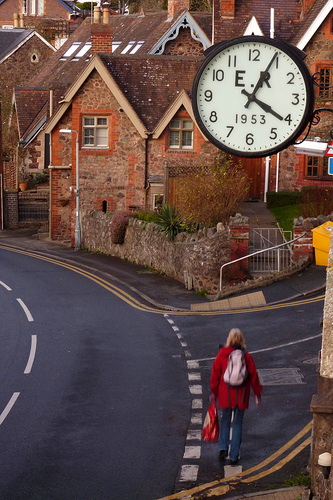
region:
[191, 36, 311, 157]
black and white clock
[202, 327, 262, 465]
person walking in the street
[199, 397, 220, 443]
bag is red and white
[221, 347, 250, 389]
backpack is white and black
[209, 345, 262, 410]
the coat is red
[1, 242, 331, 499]
the road is white and yellow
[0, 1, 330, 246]
houses on hilltop made of stone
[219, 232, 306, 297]
metal bars on stone steps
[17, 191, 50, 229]
brick steps by road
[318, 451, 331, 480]
light sconce on bottom corner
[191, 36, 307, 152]
round clock on right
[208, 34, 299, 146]
digits on white clock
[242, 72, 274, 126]
black arms on clock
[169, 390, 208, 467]
whtie lines on road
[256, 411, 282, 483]
yellow lines on road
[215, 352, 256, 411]
red jacket on woman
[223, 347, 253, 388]
pink backpack on woman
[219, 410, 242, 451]
blue jeans on woman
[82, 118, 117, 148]
small window on house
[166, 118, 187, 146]
small window on house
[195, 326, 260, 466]
woman wearing blue jeans and red jacket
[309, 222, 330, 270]
yellow trash receptacle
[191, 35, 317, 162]
round public clock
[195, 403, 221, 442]
red shopping bag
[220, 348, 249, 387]
light colored backpack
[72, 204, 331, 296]
a fence made of stone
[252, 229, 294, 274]
a metal gate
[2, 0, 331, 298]
a group of brick houses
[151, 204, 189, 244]
a small palm tree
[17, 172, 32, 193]
a clay flowerpot with plant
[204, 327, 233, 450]
this is a woman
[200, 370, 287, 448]
this is a jacket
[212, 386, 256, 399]
the jacket is red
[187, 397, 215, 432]
this is a red bag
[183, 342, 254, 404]
this is a backpack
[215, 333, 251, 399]
the backpack is pink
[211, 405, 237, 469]
these are some jeans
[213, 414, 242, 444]
the jeans are blue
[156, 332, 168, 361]
this is a dotted line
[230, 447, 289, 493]
this is a long line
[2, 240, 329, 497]
street with curved white and yellow lines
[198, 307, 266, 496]
woman crossing street with red plastic tote bag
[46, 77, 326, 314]
reddish stone building with railing on corner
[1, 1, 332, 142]
slanted and tiled roofs forming angles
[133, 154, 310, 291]
gate, stone walls and wooden partition near front door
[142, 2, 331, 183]
black and white clock in front of houses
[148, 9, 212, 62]
decorative gray gingerbread border under roof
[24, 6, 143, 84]
line of windows along slanted roof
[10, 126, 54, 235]
brick stairs leading to entryway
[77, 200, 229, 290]
brown vines leaning over long stone wall